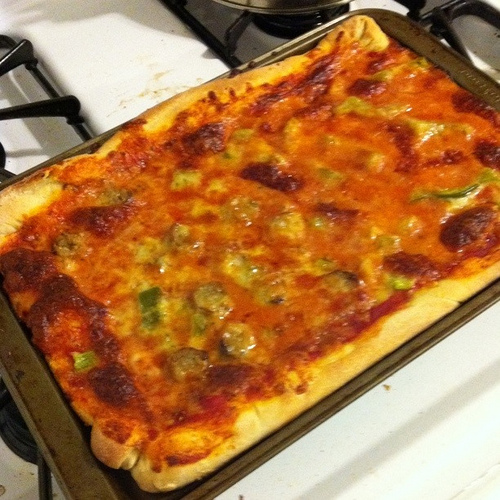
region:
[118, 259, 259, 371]
green pepper pieces in pizza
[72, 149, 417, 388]
pizza made with cheese and pepper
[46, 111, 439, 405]
large rectangular pizza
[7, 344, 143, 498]
metal dirty pie pan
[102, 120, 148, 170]
crispy bits of cheese on edge of pizza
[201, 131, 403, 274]
orange melted cheese on pizza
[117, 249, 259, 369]
cheese and pepper pieces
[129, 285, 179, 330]
squares of green peppers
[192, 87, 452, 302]
melted cheese topping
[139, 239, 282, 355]
melted cheese and peppers topping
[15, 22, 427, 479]
egg casserole in a pan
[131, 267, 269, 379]
chunks of green pepper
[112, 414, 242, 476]
crust baked in the oven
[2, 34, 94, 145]
stove burner on the stove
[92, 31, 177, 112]
dirty spot on the stove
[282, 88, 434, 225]
melted cheese on casserole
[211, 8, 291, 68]
stove burner on white stove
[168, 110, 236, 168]
cheese bubble on cassrole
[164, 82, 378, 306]
casserole just removed from the oven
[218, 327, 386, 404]
crust that has been browned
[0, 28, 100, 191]
a black stove grate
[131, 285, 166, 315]
a green pepper on the pizza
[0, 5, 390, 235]
the crust of a pizza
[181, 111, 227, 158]
a brown bubble on the pizza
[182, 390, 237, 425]
red tomato sauce on the pizza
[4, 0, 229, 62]
a shadow on the stove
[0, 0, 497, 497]
a white metal stove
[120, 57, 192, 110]
brown stains on the stove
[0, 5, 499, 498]
a gray metal baking sheet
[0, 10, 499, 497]
a pizza in the baking sheet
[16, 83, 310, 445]
A pizza is visible.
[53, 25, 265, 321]
A pizza is visible.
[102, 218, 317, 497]
A pizza is visible.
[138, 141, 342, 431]
A pizza is visible.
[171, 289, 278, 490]
A pizza is visible.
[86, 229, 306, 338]
The food has green peppes on top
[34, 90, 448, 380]
The pan is sitting on top of th stove.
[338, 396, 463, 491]
The stove is white.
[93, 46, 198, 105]
The stove has a dirty spot.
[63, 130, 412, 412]
The food is in the pan.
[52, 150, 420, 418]
The food has cheese on top.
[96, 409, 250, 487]
The crust on the food is well done.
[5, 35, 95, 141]
The burners on the stove are black.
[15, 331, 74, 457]
The pan has food stains on it.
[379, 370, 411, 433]
Crumbs are on top of the stove